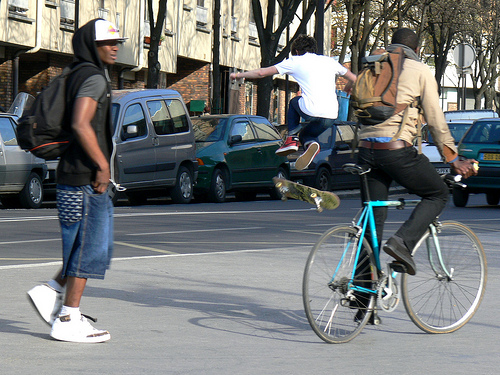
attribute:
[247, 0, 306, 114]
tree — big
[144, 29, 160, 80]
tree stem — black, big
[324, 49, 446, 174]
backpack — large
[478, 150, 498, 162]
plate — license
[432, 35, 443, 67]
tree — black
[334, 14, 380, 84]
stem — black, big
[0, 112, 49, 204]
car — parked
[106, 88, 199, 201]
car — parked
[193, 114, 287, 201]
car — parked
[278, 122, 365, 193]
car — parked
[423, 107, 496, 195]
car — parked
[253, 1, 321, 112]
tree — big, black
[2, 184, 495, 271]
road — grey, marked, tarmac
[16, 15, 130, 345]
man — large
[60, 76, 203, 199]
car — parked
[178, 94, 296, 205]
car — parked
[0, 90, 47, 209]
car — parked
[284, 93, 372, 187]
car — parked